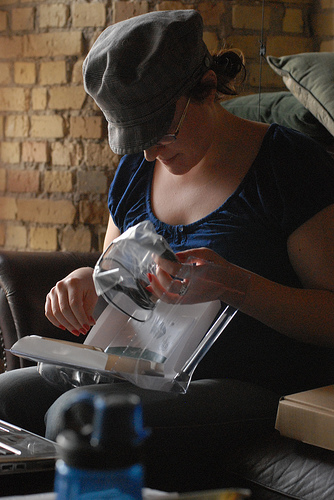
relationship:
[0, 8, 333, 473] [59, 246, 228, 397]
woman opening plastic box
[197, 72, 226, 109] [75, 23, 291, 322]
ear of a person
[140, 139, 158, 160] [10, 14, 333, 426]
nose of a person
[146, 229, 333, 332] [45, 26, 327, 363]
hand of a person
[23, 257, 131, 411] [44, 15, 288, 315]
fingers of a person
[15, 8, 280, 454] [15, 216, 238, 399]
woman unpacking unpacking electronic device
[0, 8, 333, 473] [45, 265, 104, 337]
woman has hand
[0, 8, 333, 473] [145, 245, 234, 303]
woman has hand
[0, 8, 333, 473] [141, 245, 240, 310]
woman looking at hand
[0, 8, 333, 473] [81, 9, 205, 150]
woman wearing cap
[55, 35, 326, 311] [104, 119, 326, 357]
woman wearing blouse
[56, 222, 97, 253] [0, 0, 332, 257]
brick in wall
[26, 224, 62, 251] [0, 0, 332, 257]
brick in wall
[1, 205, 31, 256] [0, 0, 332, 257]
brick in wall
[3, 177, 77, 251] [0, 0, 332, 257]
brick in wall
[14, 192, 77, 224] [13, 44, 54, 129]
brick in wall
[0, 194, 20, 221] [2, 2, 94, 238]
brick in wall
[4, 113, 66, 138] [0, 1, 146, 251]
brick in wall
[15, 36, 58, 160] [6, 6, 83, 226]
brick in wall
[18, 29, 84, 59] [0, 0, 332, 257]
brick in wall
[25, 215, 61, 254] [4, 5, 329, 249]
brick in building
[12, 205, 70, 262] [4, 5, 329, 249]
brick in building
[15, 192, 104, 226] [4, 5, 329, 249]
brick in building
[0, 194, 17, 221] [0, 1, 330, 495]
brick in building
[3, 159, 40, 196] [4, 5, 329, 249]
brick in building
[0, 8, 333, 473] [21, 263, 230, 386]
woman opens package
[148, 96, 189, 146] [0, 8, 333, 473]
glasses on woman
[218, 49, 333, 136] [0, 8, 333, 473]
pillows behind woman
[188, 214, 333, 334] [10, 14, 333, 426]
arm of person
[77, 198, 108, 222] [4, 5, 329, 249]
brick on building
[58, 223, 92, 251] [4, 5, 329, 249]
brick on building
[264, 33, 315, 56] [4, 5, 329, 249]
brick on building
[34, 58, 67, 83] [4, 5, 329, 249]
brick on building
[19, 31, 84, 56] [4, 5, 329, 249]
brick on building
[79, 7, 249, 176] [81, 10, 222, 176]
head of person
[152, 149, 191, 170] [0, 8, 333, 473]
mouth of woman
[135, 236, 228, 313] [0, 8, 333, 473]
hand of woman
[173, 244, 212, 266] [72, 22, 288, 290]
thumb of person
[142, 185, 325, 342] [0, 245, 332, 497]
arm of sofa